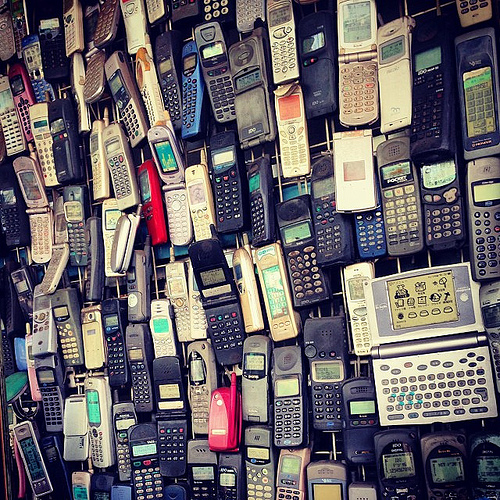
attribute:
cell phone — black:
[277, 160, 372, 259]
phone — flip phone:
[142, 121, 191, 249]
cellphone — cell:
[201, 138, 245, 231]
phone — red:
[203, 365, 249, 456]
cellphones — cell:
[5, 9, 498, 499]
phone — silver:
[163, 245, 193, 342]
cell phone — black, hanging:
[213, 147, 245, 226]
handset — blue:
[174, 41, 209, 149]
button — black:
[188, 77, 194, 85]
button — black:
[187, 77, 190, 85]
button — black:
[184, 97, 194, 107]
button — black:
[189, 109, 194, 119]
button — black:
[179, 106, 189, 112]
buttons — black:
[213, 169, 274, 229]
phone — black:
[277, 191, 332, 305]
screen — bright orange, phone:
[274, 92, 308, 119]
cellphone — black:
[128, 417, 170, 498]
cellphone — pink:
[17, 322, 44, 399]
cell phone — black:
[373, 420, 421, 498]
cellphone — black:
[305, 318, 352, 431]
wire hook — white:
[214, 27, 234, 37]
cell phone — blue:
[175, 36, 207, 142]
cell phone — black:
[147, 28, 415, 242]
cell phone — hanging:
[80, 29, 385, 171]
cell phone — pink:
[194, 138, 263, 243]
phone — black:
[345, 387, 375, 467]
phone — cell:
[302, 320, 352, 433]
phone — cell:
[181, 169, 219, 243]